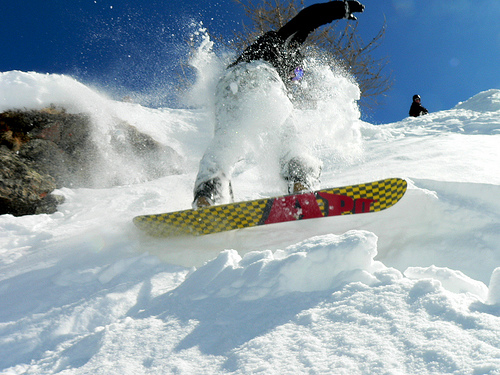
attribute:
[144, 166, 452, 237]
snowboard — checked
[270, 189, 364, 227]
letters — red, gray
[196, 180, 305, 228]
snowboard — bottom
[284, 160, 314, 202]
boot — snowboarder's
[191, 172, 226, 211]
boot — snowboarder's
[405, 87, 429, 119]
person — looking down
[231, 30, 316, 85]
coat — black, winter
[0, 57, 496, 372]
snow — deep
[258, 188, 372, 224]
letters — red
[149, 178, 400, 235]
pattern — black, gold, checkerboard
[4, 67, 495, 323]
mountain — snowy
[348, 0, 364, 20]
glove — black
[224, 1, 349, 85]
jacket — black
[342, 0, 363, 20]
gloves — black